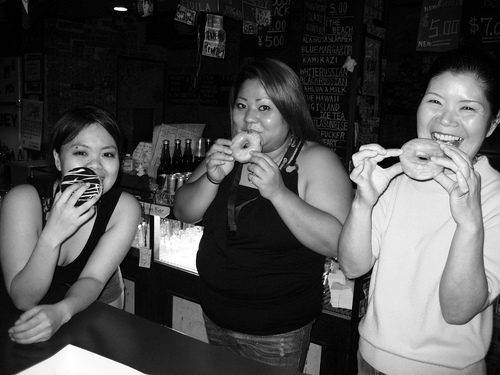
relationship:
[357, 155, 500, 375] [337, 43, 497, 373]
shirt on woman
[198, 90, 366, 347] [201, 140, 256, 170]
lady eats donut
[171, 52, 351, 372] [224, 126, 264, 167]
woman eats donut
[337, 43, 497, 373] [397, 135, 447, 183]
woman eats donut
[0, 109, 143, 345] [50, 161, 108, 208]
woman eats donut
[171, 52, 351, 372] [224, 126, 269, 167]
woman eats donut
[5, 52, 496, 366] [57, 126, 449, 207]
people eats donuts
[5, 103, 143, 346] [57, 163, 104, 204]
woman eats donut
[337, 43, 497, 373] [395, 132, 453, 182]
woman eats donut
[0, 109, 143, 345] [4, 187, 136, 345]
woman eats top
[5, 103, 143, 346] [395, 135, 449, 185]
woman eats donut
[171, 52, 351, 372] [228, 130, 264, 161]
woman eats donut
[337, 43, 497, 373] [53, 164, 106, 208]
woman eats donut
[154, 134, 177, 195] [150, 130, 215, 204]
beer bottle in row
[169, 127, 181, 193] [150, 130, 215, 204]
beer bottle in row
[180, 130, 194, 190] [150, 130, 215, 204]
beer bottle in row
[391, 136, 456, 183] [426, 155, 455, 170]
donut being held by fingers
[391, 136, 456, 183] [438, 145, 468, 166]
donut being held by fingers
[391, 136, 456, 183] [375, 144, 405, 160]
donut being held by fingers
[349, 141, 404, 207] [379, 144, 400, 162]
hand with fingers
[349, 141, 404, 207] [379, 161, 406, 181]
hand with fingers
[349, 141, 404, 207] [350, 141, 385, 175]
hand with fingers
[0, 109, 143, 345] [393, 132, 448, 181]
woman eating donut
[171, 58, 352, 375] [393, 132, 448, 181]
woman eating donut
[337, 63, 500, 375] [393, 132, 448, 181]
woman eating donut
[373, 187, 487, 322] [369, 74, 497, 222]
shirt on woman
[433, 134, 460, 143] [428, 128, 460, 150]
teeth in mouth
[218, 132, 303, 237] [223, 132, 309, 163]
lanyard around neck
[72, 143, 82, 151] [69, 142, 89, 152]
dot on eyelid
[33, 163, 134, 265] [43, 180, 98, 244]
donut held in hand